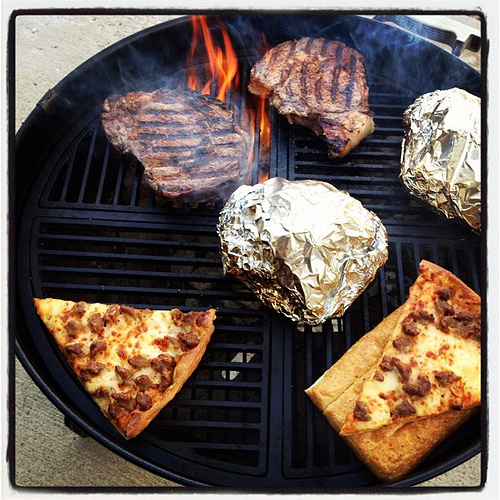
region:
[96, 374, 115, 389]
White cheese melted on pizza.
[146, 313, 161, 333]
White cheese melted on pizza.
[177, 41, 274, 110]
Red flames coming out of grill.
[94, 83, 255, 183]
Piece of meat on the grill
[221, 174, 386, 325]
A potato on the grill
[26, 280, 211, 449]
Piece of pizza on the grill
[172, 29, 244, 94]
Fire coming from a grill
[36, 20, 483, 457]
Food on a grill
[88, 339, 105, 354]
Topping on a pizza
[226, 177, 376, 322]
The potato is in foil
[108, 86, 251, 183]
The steak is on a grill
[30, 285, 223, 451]
The pizza is on a grill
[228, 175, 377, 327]
The potato is on the grill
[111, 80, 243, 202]
Steak sitting on a grill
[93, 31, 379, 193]
Two steaks on grill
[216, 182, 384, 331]
Object in aluminum foil on grill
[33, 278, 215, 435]
Slice of pizza on grill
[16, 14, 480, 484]
Grill cooking lots of food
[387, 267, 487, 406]
Slice of sausage pizza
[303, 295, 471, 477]
Slice of sausage pizza on breadsticks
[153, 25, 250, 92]
Fire coming out of a grill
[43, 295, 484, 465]
Two slices of pizza on a grill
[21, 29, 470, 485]
Black metal grill cooking food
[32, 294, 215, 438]
Slice of pizza on a grill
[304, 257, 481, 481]
Slice of pizza and breadsticks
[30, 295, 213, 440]
Pizza with cheese and sausage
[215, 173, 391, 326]
Food wrapped in foil on a grill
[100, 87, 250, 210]
Steak cooking on a grill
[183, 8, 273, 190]
Flames coming from a grill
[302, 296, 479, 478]
Four breadsticks on a grill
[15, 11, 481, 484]
Black charcoal barbeque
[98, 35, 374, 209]
Two steaks on a grill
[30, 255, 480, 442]
Two slices of pizza reheated on a grill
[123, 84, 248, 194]
piece of steak on grill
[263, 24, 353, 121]
piece of steak on grill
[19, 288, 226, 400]
slice of pizza on grill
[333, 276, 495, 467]
slice of pizza on grill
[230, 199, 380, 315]
food wrapped in foil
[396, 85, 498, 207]
food wrapped in foil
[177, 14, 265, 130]
orange flame coming out of grill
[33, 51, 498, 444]
round black cooking grill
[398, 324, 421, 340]
pieces of sausage on pizza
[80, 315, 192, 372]
melted cheese on pizza